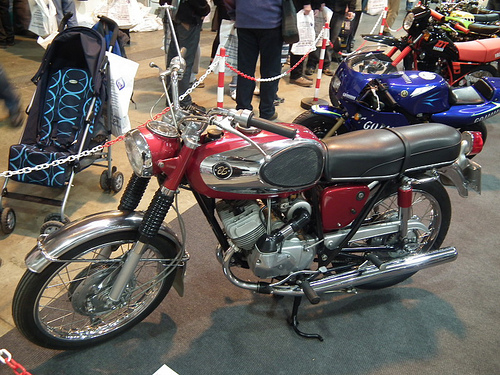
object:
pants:
[236, 25, 283, 118]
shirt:
[232, 0, 283, 28]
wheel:
[331, 171, 453, 290]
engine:
[209, 196, 323, 281]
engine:
[328, 72, 449, 130]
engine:
[426, 56, 457, 78]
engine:
[439, 11, 477, 36]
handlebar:
[198, 104, 295, 144]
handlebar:
[167, 56, 185, 76]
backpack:
[91, 21, 139, 112]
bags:
[27, 0, 58, 38]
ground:
[368, 116, 409, 161]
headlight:
[123, 127, 156, 177]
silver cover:
[23, 207, 188, 298]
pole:
[216, 47, 225, 108]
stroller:
[0, 14, 124, 238]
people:
[222, 0, 299, 121]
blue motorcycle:
[291, 50, 500, 159]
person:
[288, 0, 314, 87]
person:
[305, 0, 338, 77]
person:
[166, 0, 211, 114]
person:
[382, 0, 398, 37]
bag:
[290, 8, 317, 55]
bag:
[210, 19, 238, 76]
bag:
[366, 1, 388, 15]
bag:
[314, 4, 334, 48]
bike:
[12, 47, 485, 353]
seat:
[320, 123, 461, 181]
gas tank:
[183, 122, 324, 200]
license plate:
[466, 160, 482, 195]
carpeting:
[0, 109, 500, 375]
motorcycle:
[361, 6, 500, 87]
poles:
[312, 22, 330, 102]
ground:
[171, 315, 274, 358]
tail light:
[466, 131, 484, 155]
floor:
[0, 29, 498, 374]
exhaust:
[219, 242, 459, 295]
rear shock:
[397, 185, 413, 242]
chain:
[0, 8, 384, 182]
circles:
[61, 67, 88, 94]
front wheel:
[12, 230, 180, 352]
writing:
[34, 71, 96, 161]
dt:
[209, 196, 311, 281]